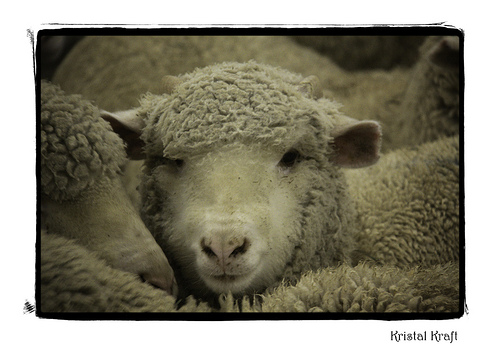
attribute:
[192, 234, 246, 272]
nose — pink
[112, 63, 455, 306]
sheep — wooly, white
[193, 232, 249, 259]
nose — pink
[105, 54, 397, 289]
sheep — tan